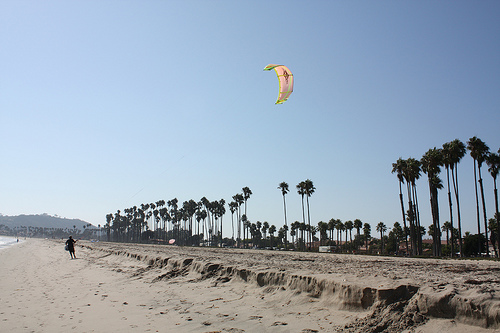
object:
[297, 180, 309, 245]
palm tree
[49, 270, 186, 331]
sand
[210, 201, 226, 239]
palm trees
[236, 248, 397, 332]
sand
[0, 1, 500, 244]
sky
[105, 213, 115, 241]
trees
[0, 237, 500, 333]
beach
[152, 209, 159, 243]
trees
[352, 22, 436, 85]
clear and blue sky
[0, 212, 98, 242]
bunch of mountains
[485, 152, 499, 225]
palm trees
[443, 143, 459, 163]
palm tree leaves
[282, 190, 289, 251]
skinny trunk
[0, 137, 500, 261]
ridge made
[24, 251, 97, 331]
foot prints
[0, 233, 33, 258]
ocean hitting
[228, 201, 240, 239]
palm trees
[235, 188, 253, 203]
leaves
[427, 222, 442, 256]
trunks of palm trees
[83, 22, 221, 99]
clear and blue sky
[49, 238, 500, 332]
ledge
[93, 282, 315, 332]
bunch of foot prints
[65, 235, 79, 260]
guy standing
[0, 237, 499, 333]
shore of the beach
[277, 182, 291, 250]
"a palm tree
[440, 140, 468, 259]
palm tree on the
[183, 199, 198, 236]
palm trees on beach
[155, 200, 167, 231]
palm trees on beach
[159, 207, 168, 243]
trees on the edge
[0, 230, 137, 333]
edge a beach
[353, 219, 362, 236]
trees on the edge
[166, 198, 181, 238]
trees on the beach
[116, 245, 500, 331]
sand elevated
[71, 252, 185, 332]
area of the beach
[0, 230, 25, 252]
water area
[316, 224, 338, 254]
buildings behind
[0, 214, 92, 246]
terrain in the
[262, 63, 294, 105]
fabric in the air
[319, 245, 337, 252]
white toilet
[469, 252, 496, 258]
white toilet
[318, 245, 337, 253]
toilet in th bathroo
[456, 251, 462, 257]
white toilet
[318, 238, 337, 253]
bathroom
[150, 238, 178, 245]
bathroom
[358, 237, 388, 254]
bathroom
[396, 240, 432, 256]
bathroom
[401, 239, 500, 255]
bathroom